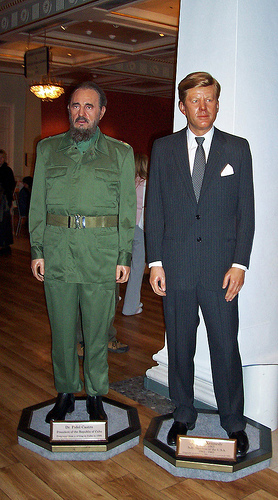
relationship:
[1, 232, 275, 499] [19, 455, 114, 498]
floor has board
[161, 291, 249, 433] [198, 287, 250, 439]
trouser has leg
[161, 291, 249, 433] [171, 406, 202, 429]
trouser has edge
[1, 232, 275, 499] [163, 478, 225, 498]
floor has board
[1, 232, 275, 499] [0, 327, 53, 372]
floor has board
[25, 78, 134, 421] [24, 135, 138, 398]
figure in uniform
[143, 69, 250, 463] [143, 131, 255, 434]
statue in suit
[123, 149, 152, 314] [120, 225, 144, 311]
woman wearing jeans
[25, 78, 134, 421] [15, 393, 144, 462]
figure on base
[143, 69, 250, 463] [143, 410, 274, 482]
statue on base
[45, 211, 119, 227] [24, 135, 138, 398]
belt in uniform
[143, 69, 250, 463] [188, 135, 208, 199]
statue has tie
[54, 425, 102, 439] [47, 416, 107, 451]
writing on plate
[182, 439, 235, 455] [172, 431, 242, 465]
writing on plate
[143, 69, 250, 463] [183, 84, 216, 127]
statue has face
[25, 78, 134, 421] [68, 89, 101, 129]
figure has face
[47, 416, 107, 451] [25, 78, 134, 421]
plate on statue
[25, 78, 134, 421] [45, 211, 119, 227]
figure wearing belt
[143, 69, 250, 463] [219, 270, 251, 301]
statue has hand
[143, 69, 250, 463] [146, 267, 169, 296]
statue has hand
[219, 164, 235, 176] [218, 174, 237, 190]
handkerchief in pocket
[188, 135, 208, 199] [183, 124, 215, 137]
tie around neck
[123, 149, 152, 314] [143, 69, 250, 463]
woman behind statue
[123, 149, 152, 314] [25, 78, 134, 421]
woman behind figure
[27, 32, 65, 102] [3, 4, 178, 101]
light hangs from ceiling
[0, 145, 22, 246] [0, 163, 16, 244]
person wearing clothes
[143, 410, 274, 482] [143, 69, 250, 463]
pedestal for statue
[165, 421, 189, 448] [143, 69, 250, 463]
shoe on statue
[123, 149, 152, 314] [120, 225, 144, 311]
woman wearing pants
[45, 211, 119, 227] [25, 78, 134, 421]
belt on figure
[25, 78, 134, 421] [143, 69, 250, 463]
figure are statue